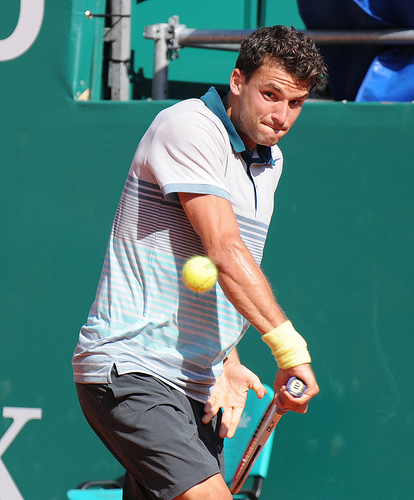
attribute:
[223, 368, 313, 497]
racket — white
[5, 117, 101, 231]
wall — green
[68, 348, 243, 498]
shorts — grey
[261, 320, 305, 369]
wristband — yellow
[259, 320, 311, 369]
wristband — yellow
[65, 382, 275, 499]
chair — green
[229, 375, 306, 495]
racket — white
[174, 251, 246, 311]
ball — yellow